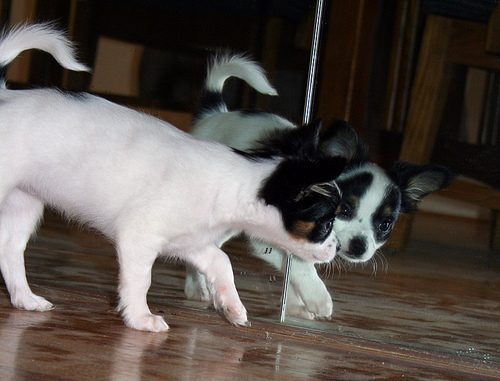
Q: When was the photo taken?
A: Day time.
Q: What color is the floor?
A: Brown.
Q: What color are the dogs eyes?
A: Black.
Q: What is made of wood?
A: The floor.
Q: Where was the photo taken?
A: In a room.